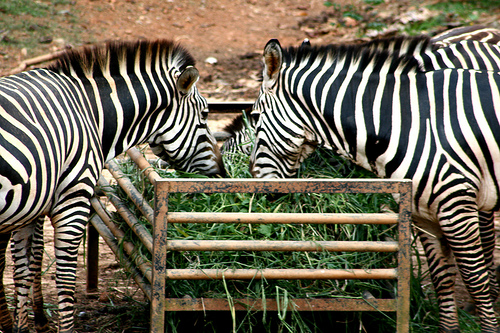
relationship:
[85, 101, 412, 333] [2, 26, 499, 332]
crate for zebras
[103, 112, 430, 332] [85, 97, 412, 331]
grass in crate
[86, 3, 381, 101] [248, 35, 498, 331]
dirt ground above zebra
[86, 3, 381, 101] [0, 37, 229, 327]
dirt ground above zebra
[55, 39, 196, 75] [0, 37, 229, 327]
maine of zebra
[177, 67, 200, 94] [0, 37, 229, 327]
ear of zebra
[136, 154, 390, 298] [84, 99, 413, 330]
grass in feeding square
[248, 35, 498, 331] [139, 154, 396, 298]
zebra eating grass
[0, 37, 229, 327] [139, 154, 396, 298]
zebra eating grass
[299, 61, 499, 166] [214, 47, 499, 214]
stripes on zebra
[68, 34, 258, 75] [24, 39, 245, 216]
maine on zebra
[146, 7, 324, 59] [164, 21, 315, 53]
gravel on ground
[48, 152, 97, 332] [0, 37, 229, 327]
leg of zebra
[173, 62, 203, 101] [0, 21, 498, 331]
ear of zebra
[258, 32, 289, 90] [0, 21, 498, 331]
ear of zebra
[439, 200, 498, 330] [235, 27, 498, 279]
leg of zebra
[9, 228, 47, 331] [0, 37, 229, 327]
leg of zebra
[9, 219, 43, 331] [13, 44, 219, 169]
leg of zebra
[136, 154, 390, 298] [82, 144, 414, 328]
grass in fence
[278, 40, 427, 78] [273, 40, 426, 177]
mane on neck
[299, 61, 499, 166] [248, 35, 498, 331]
stripes on zebra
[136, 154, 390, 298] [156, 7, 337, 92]
grass growing on ground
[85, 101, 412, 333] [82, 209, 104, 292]
crate has legs